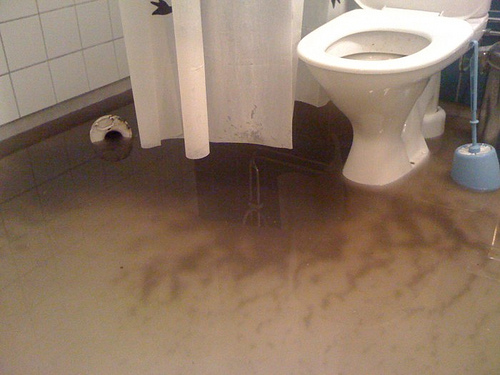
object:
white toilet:
[296, 0, 492, 188]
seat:
[297, 4, 476, 75]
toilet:
[295, 0, 492, 193]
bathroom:
[1, 0, 500, 375]